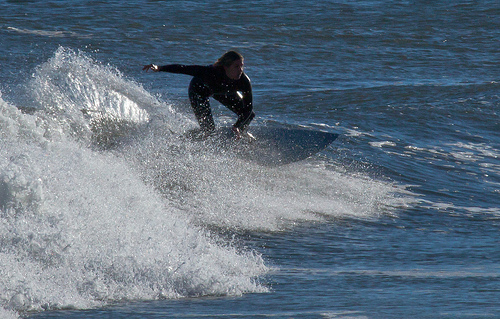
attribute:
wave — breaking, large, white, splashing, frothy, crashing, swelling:
[3, 103, 177, 303]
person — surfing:
[143, 52, 258, 148]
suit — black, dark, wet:
[157, 65, 256, 140]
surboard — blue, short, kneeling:
[188, 125, 340, 168]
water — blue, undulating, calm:
[0, 1, 499, 316]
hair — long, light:
[208, 50, 243, 72]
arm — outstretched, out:
[144, 60, 212, 78]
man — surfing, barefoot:
[141, 49, 257, 153]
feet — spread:
[177, 130, 257, 144]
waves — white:
[2, 56, 280, 301]